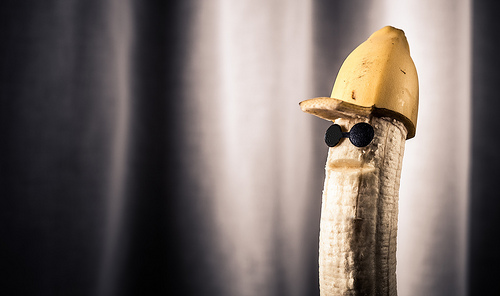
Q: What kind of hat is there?
A: Banana.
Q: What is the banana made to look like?
A: Construction worker.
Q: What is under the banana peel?
A: Fake eyes.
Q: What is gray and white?
A: Curtain.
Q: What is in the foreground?
A: A banana.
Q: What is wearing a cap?
A: Banana.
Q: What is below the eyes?
A: Banana's mouth.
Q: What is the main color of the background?
A: Grey.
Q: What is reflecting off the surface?
A: Light.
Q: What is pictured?
A: Banana.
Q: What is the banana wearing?
A: Peel cap.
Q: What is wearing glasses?
A: A banana.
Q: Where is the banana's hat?
A: On top of it.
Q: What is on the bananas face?
A: Sunglasses.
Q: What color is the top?
A: Yellow.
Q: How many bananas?
A: One.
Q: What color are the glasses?
A: Black.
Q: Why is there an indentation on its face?
A: For a mouth.